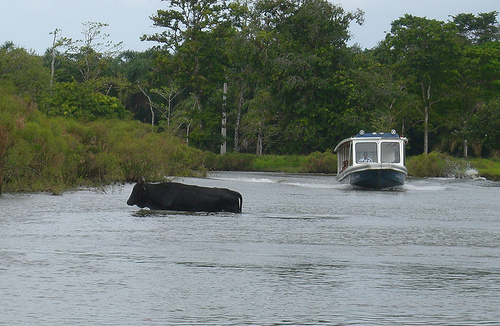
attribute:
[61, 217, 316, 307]
water — blue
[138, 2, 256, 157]
tree — bushy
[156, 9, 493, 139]
trees — brown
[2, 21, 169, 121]
trees — brown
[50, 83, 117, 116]
leaves — green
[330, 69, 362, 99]
leaves — green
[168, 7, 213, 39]
leaves — green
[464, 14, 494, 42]
leaves — green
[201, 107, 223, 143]
leaves — green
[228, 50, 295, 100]
leaves — green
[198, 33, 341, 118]
trees — brown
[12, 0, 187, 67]
sky — blue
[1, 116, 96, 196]
tree — bushy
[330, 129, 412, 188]
boat — blue, white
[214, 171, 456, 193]
waves — white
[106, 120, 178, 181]
tree — bushy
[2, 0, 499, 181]
leaves — green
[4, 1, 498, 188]
trees — brown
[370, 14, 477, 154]
tree — bushy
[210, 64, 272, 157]
trunk — tall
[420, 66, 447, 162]
trunk — tall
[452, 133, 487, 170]
trunk — tall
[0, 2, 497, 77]
sky — blue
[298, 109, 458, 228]
boat — silver, blue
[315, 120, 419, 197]
boat — white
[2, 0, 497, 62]
sky — blue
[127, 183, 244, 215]
yak — large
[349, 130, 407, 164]
frame — white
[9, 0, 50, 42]
clouds — white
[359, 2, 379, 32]
clouds — white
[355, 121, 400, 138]
lights — clear